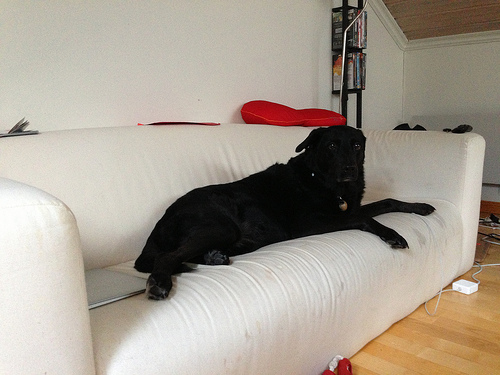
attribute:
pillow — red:
[240, 98, 349, 131]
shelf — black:
[326, 0, 376, 135]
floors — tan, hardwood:
[329, 241, 496, 371]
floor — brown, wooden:
[394, 304, 493, 374]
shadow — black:
[401, 101, 498, 205]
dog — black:
[86, 95, 410, 245]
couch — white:
[6, 117, 383, 373]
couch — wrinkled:
[39, 133, 493, 318]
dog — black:
[136, 127, 431, 277]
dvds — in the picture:
[332, 6, 367, 93]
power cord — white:
[424, 230, 499, 330]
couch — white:
[25, 107, 413, 321]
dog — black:
[161, 129, 381, 270]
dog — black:
[131, 123, 433, 300]